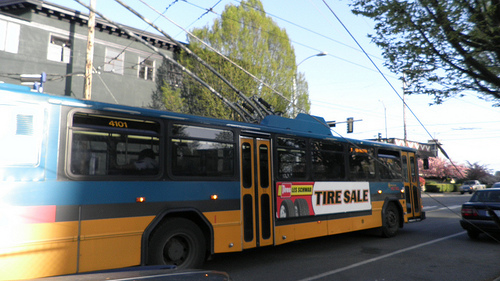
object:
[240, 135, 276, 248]
door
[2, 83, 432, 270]
bus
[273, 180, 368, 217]
sign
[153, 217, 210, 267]
black tire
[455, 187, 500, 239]
car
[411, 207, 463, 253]
line on road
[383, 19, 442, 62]
leaves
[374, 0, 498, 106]
tree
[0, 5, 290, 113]
building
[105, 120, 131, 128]
number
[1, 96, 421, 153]
top of bus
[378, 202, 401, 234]
wheel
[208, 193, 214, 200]
light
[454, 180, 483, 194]
parked car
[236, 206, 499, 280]
road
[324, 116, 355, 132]
traffic signal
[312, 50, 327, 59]
light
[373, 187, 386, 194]
light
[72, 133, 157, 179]
window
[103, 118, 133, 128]
orange letters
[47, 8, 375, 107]
wires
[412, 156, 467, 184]
trees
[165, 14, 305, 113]
tree